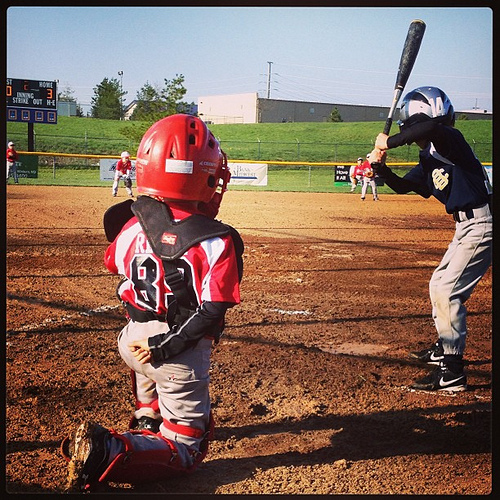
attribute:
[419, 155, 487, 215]
logo — white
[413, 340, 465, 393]
sneakers — black, white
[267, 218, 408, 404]
dirt — red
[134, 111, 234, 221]
helmet — red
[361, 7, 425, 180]
bat — black, silver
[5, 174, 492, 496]
earth — red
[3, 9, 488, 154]
sky — mostly clear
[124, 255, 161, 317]
number — black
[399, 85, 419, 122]
helmet — silver, black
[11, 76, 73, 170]
board — black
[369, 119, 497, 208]
shirt — black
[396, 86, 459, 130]
helmet — silver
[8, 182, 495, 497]
dirt — red